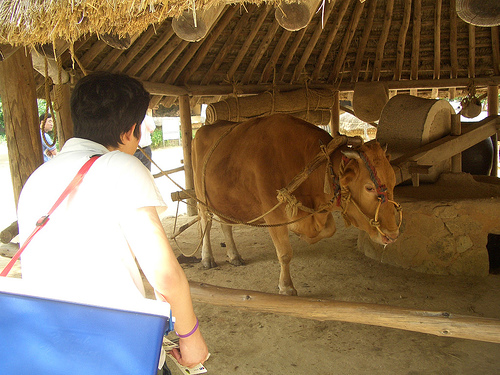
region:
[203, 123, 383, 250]
this is a cow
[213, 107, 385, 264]
the cow is brown in color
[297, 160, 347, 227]
the cow is tied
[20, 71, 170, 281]
this is a man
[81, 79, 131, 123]
this is the hair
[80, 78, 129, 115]
the hair is the black in color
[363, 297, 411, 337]
this is a pole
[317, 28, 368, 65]
this is the roof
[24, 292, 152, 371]
this is a bag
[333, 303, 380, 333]
the pole is wooden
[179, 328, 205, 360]
part of a handle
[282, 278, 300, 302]
[art of a hoof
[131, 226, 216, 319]
part of an elbow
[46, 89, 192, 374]
this is a man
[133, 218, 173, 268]
the man is light skinned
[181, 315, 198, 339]
this is a wrist band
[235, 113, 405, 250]
this is a cow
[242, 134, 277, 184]
the cow is brown in color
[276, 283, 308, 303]
this is the heels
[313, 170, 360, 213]
this is a rope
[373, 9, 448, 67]
this is the roof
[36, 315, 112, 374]
this is a vetenary kit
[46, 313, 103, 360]
the kit is blue in color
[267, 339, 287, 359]
part of a ground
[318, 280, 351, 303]
part of a ground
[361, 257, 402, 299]
part of a floor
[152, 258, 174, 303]
part of an elbow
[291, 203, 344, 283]
part of a chest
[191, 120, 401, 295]
a brown cow standing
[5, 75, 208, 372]
person with a blue bag over shoulder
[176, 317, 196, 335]
purple wrist band on person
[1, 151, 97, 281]
a red shoulder strap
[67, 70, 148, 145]
the person's dark brown hair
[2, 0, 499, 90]
thatch roof over the cow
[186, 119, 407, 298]
Brown cow wearing halter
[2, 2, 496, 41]
Roof made of straw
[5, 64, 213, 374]
Woman with black hair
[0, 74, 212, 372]
Woamn wearing white shirt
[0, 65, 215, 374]
Woman carring a blue cooler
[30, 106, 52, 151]
Man with dark hair in background